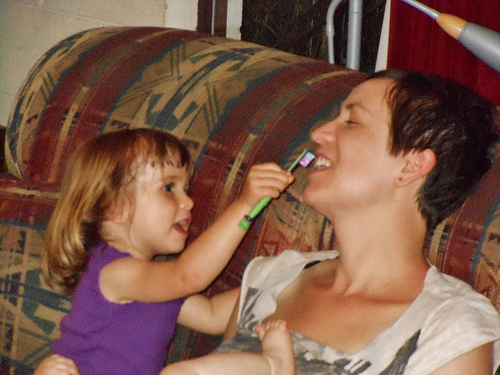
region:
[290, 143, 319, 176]
top of green and orange toothbrush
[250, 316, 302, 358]
little girl's feet with toes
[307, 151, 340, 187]
mouth with red lipstick smiling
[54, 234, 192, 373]
little girl's purple top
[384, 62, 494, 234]
woman's short black hair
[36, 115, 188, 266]
little girl's medium blond hair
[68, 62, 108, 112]
portion of sofa with red and gold colors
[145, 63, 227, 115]
portion of sofa with black and gold colors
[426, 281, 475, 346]
white portion of shirt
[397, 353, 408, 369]
black portion of shirt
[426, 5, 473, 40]
orange portion of appliance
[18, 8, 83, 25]
portion of tan wall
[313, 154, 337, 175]
woman's smiling teeth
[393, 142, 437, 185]
woman's white ear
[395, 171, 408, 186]
small hole in woman's ear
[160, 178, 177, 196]
child's black colored eye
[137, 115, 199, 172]
child's short dark brown bangs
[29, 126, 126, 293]
child's long dark blond hair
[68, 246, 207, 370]
child's purple shirt without sleeves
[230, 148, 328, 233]
green toothbrush with black marking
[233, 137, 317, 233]
A green toothbrush.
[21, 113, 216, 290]
A girl with long hair.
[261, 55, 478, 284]
A mom having her teeth cleaned.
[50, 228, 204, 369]
A purple shirt.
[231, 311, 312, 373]
A babies foot.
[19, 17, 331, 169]
A multi-colored couch.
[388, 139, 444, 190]
An ear with a small earing.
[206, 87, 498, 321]
A woman smiling.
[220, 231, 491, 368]
A white and gray shirt.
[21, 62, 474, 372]
A mom with short hair and a daughter with long.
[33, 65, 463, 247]
little girl trying to brush lady's teeth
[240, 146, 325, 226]
a green toothbrush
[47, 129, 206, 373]
little girl wearing purple shirt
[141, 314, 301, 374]
a babies leg and foot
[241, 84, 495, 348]
a woman wearing a white and grey shirt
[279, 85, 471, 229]
a woman laughing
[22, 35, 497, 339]
two people sitting on a couch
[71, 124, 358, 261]
child holding toothbrush to woman's mouth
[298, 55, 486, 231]
a woman with a short hair cut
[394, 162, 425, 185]
tiny earrings in a ear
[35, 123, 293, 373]
little girl with brown hair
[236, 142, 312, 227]
a tooth brush in the little girl hand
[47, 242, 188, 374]
little girl wearing a purple short sleeve sweater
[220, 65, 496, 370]
a lady wearing a white short sleeve blouse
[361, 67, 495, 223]
a lady with short black hair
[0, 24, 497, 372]
a red, brown, blue and white sofa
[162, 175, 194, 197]
blue eyes and long eye lids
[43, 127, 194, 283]
little girl with a beautiful smile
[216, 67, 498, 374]
a woman with white teeth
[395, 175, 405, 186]
a woman with her ear pierced